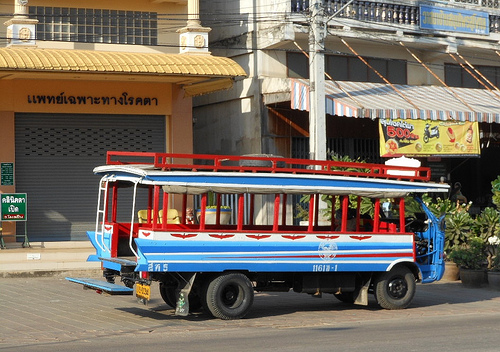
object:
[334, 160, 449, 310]
front portion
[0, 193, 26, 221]
sign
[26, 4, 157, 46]
window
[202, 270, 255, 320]
tire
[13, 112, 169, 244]
garage door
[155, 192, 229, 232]
window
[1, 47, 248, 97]
awning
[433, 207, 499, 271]
plant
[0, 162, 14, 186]
sign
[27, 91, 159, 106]
lettering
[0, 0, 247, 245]
building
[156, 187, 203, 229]
window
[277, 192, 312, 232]
window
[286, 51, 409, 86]
window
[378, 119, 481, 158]
banner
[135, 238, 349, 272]
letters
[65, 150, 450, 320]
bus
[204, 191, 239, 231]
window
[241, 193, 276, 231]
window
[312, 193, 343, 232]
window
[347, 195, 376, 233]
window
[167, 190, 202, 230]
window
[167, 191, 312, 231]
window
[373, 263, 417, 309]
wheel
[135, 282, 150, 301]
number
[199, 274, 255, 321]
wheel